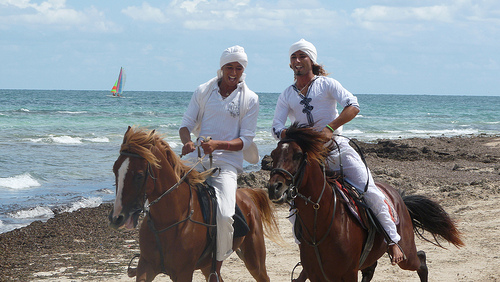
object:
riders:
[175, 39, 411, 281]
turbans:
[218, 39, 317, 68]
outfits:
[178, 76, 401, 262]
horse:
[109, 126, 284, 282]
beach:
[0, 132, 500, 281]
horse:
[266, 121, 465, 282]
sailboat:
[105, 66, 132, 99]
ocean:
[0, 88, 500, 233]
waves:
[37, 130, 97, 147]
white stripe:
[111, 156, 131, 220]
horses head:
[108, 126, 157, 230]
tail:
[398, 191, 465, 249]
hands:
[179, 140, 218, 156]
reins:
[145, 137, 212, 207]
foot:
[388, 242, 408, 263]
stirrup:
[386, 237, 411, 266]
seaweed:
[5, 203, 46, 213]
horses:
[105, 121, 465, 282]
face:
[108, 151, 150, 231]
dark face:
[265, 139, 306, 205]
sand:
[272, 253, 289, 280]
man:
[179, 45, 260, 281]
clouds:
[183, 9, 245, 30]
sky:
[0, 0, 500, 97]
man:
[271, 39, 408, 266]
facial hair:
[296, 68, 304, 77]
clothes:
[177, 76, 260, 164]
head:
[217, 45, 250, 87]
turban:
[289, 39, 317, 63]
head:
[289, 39, 317, 75]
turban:
[218, 45, 249, 68]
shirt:
[176, 73, 260, 170]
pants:
[179, 147, 244, 261]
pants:
[281, 140, 402, 246]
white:
[271, 96, 298, 131]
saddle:
[197, 182, 252, 244]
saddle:
[327, 173, 402, 232]